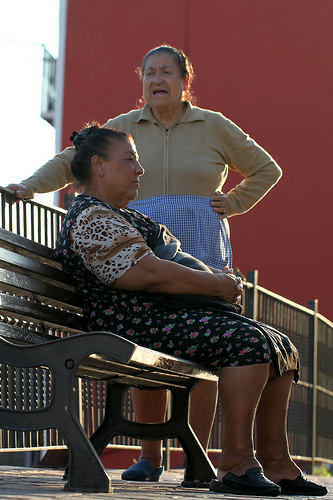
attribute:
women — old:
[0, 45, 329, 497]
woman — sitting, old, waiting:
[56, 125, 327, 496]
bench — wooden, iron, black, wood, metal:
[2, 229, 220, 494]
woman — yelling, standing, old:
[5, 44, 284, 485]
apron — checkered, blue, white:
[126, 195, 231, 270]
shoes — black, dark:
[210, 467, 328, 496]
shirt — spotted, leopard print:
[69, 201, 153, 285]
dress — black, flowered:
[56, 193, 302, 384]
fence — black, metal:
[0, 186, 332, 468]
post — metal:
[247, 269, 259, 322]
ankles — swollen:
[213, 445, 305, 481]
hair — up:
[67, 122, 133, 184]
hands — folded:
[217, 262, 244, 302]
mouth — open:
[152, 88, 170, 96]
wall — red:
[59, 4, 332, 470]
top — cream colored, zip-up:
[19, 103, 283, 215]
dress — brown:
[18, 103, 286, 216]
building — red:
[2, 3, 329, 469]